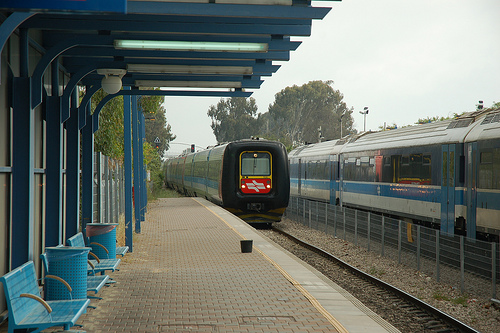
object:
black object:
[238, 238, 255, 254]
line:
[244, 249, 316, 303]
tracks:
[263, 226, 488, 332]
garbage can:
[85, 220, 117, 257]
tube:
[119, 37, 270, 56]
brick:
[182, 266, 244, 286]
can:
[45, 248, 90, 299]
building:
[4, 1, 337, 329]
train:
[160, 134, 293, 229]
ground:
[86, 167, 396, 330]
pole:
[121, 85, 133, 250]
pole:
[132, 92, 141, 232]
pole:
[137, 109, 145, 221]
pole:
[144, 167, 148, 211]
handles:
[17, 240, 107, 312]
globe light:
[100, 74, 121, 96]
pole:
[116, 89, 136, 256]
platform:
[4, 0, 396, 330]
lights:
[236, 181, 252, 192]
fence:
[268, 195, 500, 303]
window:
[32, 171, 46, 258]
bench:
[2, 228, 128, 331]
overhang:
[4, 0, 334, 100]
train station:
[2, 0, 499, 333]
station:
[0, 0, 498, 331]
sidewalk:
[0, 178, 398, 333]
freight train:
[268, 100, 500, 244]